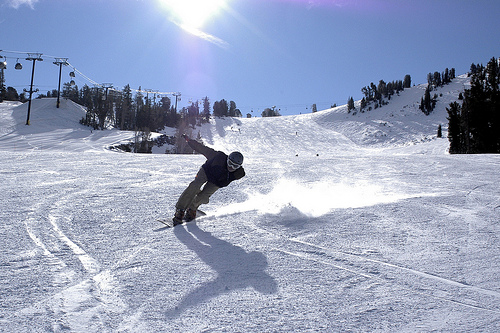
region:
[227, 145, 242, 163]
The helmet on the snowboarder's head.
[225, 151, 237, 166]
The white goggles the snowboarder is wearing.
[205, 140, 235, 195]
The jacket the snowboarder is wearing.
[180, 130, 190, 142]
The glove on the snowboarder's left hand.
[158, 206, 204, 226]
The snowboard the guy is on.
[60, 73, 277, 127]
The trees in the distance.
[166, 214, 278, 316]
The shadow of the snowboarder on the snow.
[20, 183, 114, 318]
The tracks in the snow to the left of the snowboarder.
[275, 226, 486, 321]
The tracks in the snow to the right of the snowboader's shadow on the ground.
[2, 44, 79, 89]
The ski lifts in the air.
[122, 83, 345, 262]
Man snowboarding in the winter.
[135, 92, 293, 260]
Man who is snowboarding.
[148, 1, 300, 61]
Sun in the sky.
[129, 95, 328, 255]
Man on a snowboard.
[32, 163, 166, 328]
Tracks in the snow.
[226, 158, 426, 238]
Powder in the air.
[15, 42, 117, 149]
Ski lift in the background.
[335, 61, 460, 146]
Trees on the hill.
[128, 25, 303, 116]
Blue sky behind the mountain.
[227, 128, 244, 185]
Man wearing a helmet.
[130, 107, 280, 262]
person snowboarding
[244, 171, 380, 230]
snow kicked up from the board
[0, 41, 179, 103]
ski lift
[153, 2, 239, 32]
sun brightly shining in the sky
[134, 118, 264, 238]
person leaning to the side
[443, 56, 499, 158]
dar, thick trees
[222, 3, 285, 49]
thin ray of light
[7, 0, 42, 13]
wisp of a white cloud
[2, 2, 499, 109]
bright blue sky with only a tiny bit of cloud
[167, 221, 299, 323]
shadow from the person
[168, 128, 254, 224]
skiier is skiing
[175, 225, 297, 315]
shadow in the snow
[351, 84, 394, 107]
green trees on the hill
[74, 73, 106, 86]
electrical lines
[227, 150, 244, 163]
person is wearing a helmet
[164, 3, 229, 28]
the sun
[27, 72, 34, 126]
an electrical pole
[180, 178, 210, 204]
skiier is wearing pants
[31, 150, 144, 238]
the snow is white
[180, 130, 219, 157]
the arm of the skiier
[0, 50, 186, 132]
ski lift in the distance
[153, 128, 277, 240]
man skiing down the hill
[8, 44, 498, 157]
trees on the snow covered mountain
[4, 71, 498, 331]
snow on the top of a mountain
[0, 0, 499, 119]
blue sky with no clouds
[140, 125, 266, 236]
skier going down the mountain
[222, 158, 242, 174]
white goggles on the man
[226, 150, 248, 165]
green helmet worn by the skier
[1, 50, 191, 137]
ski lift going up the mountain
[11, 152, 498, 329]
tracks left in the snow by skiers